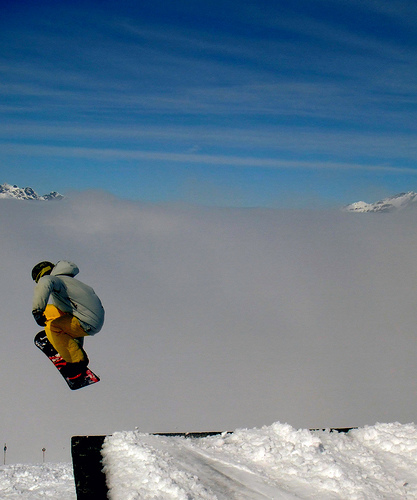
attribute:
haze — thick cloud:
[5, 190, 414, 431]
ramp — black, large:
[68, 423, 416, 499]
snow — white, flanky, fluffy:
[101, 423, 416, 497]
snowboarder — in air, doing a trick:
[26, 259, 103, 393]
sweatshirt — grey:
[30, 259, 109, 337]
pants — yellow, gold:
[36, 304, 91, 367]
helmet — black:
[30, 258, 59, 282]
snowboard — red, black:
[31, 326, 102, 395]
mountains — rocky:
[0, 172, 65, 208]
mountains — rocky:
[342, 187, 415, 215]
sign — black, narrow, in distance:
[2, 441, 11, 466]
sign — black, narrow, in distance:
[39, 441, 49, 466]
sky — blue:
[0, 1, 413, 202]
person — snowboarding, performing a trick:
[29, 254, 106, 379]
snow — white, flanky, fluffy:
[1, 457, 76, 499]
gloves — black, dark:
[29, 303, 52, 330]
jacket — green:
[28, 259, 108, 339]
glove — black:
[32, 303, 48, 328]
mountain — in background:
[0, 180, 65, 208]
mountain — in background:
[342, 184, 413, 214]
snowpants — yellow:
[40, 303, 93, 363]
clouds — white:
[255, 24, 413, 184]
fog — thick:
[1, 193, 416, 429]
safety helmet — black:
[28, 259, 55, 282]